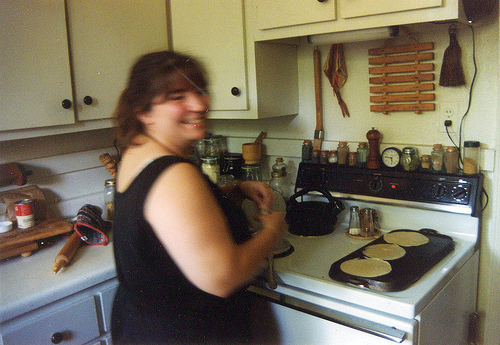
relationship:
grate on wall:
[367, 40, 438, 114] [299, 2, 500, 147]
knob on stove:
[451, 186, 468, 200] [249, 162, 483, 344]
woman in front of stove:
[111, 49, 286, 344] [249, 162, 483, 344]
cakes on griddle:
[340, 231, 431, 276] [329, 227, 454, 293]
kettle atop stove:
[286, 186, 346, 237] [249, 162, 483, 344]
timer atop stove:
[381, 147, 401, 169] [249, 162, 483, 344]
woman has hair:
[111, 49, 286, 344] [110, 51, 208, 144]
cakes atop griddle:
[340, 231, 431, 276] [329, 227, 454, 293]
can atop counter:
[15, 200, 36, 230] [0, 195, 117, 325]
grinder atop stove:
[365, 124, 382, 169] [249, 162, 483, 344]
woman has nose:
[111, 49, 286, 344] [188, 92, 207, 112]